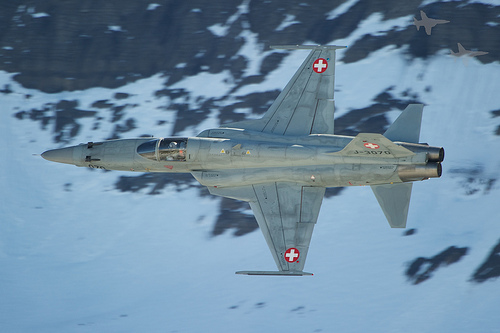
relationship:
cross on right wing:
[311, 54, 329, 75] [252, 41, 348, 135]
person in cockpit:
[165, 140, 179, 161] [137, 137, 188, 164]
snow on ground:
[0, 193, 205, 328] [0, 1, 500, 332]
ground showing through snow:
[401, 244, 469, 287] [375, 284, 498, 332]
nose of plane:
[38, 144, 74, 167] [40, 45, 444, 278]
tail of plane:
[336, 102, 443, 229] [40, 45, 444, 278]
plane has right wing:
[40, 45, 444, 278] [252, 41, 348, 135]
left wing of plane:
[224, 163, 337, 277] [40, 45, 444, 278]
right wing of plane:
[252, 41, 348, 135] [40, 45, 444, 278]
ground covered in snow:
[0, 1, 500, 332] [0, 193, 205, 328]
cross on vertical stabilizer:
[364, 142, 380, 151] [335, 131, 416, 158]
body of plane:
[197, 130, 346, 191] [40, 45, 444, 278]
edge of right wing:
[267, 42, 349, 51] [252, 41, 348, 135]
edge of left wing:
[236, 268, 314, 279] [232, 163, 329, 278]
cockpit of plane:
[137, 137, 188, 164] [40, 45, 444, 278]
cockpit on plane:
[137, 137, 188, 164] [40, 45, 444, 278]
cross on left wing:
[282, 246, 300, 265] [232, 163, 329, 278]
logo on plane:
[362, 137, 379, 154] [40, 45, 444, 278]